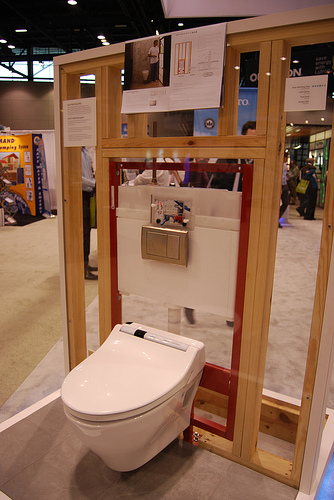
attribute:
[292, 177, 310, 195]
bag — green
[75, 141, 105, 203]
shirt — blue 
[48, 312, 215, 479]
toilet — white